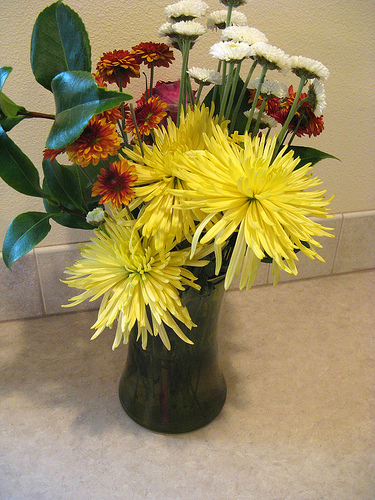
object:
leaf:
[43, 71, 134, 150]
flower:
[186, 66, 225, 86]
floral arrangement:
[0, 0, 343, 436]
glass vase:
[119, 273, 228, 433]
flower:
[209, 41, 257, 63]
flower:
[118, 102, 131, 120]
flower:
[205, 10, 248, 33]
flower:
[242, 107, 276, 128]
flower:
[288, 55, 330, 81]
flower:
[157, 21, 174, 38]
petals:
[165, 312, 194, 345]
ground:
[0, 270, 375, 500]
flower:
[134, 80, 198, 123]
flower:
[92, 72, 124, 125]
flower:
[91, 158, 139, 209]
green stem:
[177, 41, 191, 127]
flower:
[280, 85, 325, 138]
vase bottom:
[119, 371, 227, 434]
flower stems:
[129, 294, 223, 411]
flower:
[172, 20, 207, 41]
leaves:
[30, 0, 93, 94]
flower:
[42, 146, 64, 164]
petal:
[143, 278, 159, 302]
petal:
[149, 272, 170, 283]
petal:
[107, 279, 127, 305]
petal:
[62, 293, 97, 309]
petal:
[163, 267, 181, 277]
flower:
[271, 108, 309, 138]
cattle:
[166, 121, 336, 291]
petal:
[245, 213, 254, 248]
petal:
[166, 120, 335, 290]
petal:
[257, 232, 275, 260]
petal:
[205, 198, 250, 208]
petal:
[272, 194, 295, 203]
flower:
[123, 94, 167, 139]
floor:
[0, 270, 375, 499]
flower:
[165, 0, 210, 18]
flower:
[66, 115, 125, 166]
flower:
[96, 49, 143, 89]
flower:
[86, 207, 105, 226]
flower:
[166, 36, 203, 50]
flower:
[59, 204, 226, 351]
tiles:
[0, 210, 374, 323]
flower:
[132, 133, 153, 145]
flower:
[119, 101, 240, 251]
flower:
[246, 77, 289, 99]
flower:
[221, 25, 269, 47]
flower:
[129, 40, 175, 67]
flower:
[218, 0, 247, 8]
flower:
[307, 78, 326, 119]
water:
[118, 340, 227, 432]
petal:
[185, 67, 222, 85]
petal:
[287, 55, 329, 81]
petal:
[209, 40, 256, 61]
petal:
[172, 20, 207, 35]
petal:
[165, 1, 210, 19]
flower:
[248, 88, 280, 113]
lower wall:
[0, 0, 375, 316]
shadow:
[0, 243, 253, 429]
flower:
[166, 121, 336, 291]